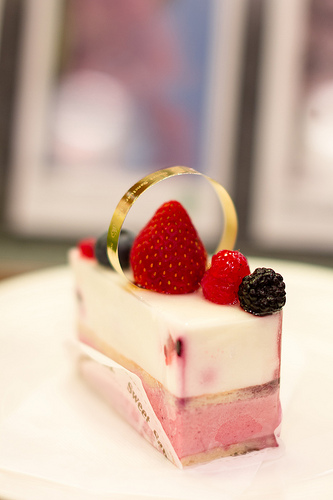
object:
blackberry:
[237, 266, 286, 318]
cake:
[68, 165, 285, 467]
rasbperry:
[200, 250, 251, 306]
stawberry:
[130, 200, 209, 293]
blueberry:
[95, 228, 136, 271]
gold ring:
[105, 166, 238, 292]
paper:
[71, 334, 286, 470]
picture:
[2, 0, 250, 255]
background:
[0, 1, 332, 498]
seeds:
[168, 242, 172, 249]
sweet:
[127, 382, 150, 423]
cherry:
[78, 239, 99, 261]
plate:
[0, 255, 332, 498]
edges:
[69, 243, 281, 471]